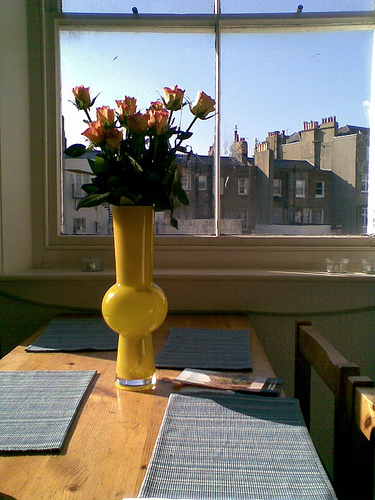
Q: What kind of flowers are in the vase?
A: Roses.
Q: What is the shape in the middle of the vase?
A: Round.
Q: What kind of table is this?
A: Kitchen.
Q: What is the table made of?
A: Wood.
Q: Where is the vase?
A: On the table.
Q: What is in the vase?
A: Roses.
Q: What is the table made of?
A: Wood.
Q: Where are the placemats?
A: On the table.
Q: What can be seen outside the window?
A: Buildings.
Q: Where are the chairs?
A: By the table.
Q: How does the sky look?
A: Cloudless.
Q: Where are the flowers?
A: In the vase.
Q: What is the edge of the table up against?
A: The wall.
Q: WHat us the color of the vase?
A: Yellow.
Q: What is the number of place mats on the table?
A: Four.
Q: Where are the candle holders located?
A: On the window sill.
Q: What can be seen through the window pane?
A: Buildings.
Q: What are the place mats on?
A: The table.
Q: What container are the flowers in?
A: The vase.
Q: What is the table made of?
A: Wood.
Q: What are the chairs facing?
A: The table.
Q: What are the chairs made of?
A: Wood.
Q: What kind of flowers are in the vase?
A: Roses.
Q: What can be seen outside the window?
A: Buildings.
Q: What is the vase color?
A: Yellow.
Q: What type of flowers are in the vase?
A: Roses.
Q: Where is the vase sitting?
A: On the table.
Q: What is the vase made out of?
A: Glass.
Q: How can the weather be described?
A: Clear.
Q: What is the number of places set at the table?
A: 4.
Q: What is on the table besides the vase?
A: Placemats.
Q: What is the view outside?
A: Buildings.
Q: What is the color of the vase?
A: Yellow.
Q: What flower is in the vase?
A: Rose.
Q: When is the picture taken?
A: Daytime.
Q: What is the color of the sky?
A: Blue.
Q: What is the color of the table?
A: Brown.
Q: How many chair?
A: 2.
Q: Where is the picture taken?
A: In the dining room.